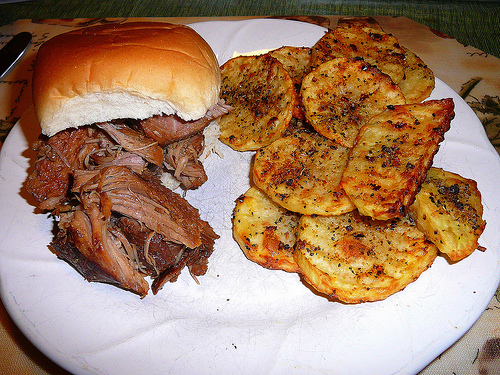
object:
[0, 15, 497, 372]
table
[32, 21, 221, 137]
bread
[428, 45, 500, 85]
ground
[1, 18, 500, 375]
dish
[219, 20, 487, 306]
chips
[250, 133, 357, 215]
slice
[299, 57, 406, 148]
slice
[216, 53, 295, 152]
slice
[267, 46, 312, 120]
slice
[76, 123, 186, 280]
strips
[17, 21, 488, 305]
food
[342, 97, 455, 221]
piece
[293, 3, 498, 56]
green top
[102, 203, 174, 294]
cracks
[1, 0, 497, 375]
furniture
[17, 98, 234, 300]
grilled meat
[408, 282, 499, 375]
edge